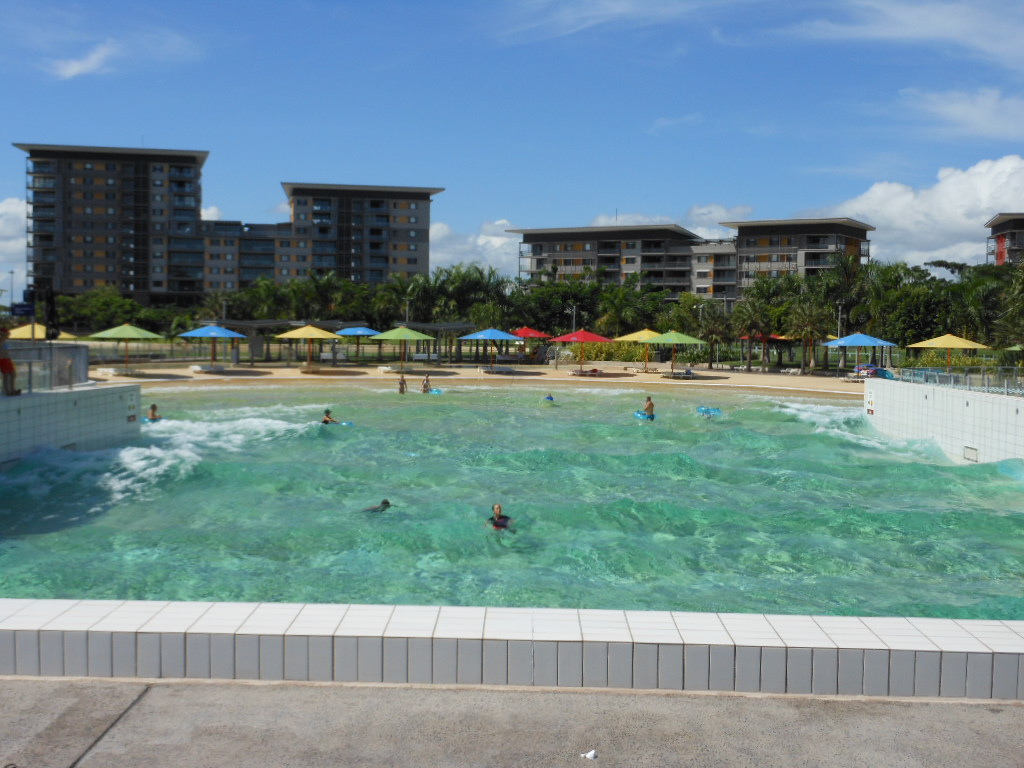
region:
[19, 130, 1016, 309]
vacation hotel building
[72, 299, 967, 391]
colorful open umbrellas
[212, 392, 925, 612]
swimmers in pool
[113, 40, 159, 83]
white clouds in blue sky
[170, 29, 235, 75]
white clouds in blue sky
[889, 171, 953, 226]
white clouds in blue sky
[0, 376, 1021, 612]
large clear swimming area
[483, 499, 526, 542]
swimmer in the water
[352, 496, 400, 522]
swimmer in the water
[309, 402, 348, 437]
swimmer in the water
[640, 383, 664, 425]
swimmer in the water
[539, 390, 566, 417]
swimmer in the water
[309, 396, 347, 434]
swimmer in the water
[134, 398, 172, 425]
swimmer in the water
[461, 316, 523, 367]
colorful beach umbrella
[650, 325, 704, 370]
colorful beach umbrella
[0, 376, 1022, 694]
large outdoor swimming pool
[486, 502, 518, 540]
person swimming in the water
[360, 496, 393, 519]
person swimming in the water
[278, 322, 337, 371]
yellow beach umbrella on the shore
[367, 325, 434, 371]
green beach umbrella on the shore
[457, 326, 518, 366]
blue beach umbrella on the shore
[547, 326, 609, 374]
red beach umbrella on the shore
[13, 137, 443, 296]
large multi story building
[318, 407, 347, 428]
person swimming in the water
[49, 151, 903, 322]
vacation buildings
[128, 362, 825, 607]
people swimming in pool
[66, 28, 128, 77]
white clouds in blue sky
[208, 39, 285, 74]
white clouds in blue sky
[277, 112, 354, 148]
white clouds in blue sky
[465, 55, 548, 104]
white clouds in blue sky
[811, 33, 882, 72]
white clouds in blue sky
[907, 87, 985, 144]
white clouds in blue sky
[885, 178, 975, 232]
white clouds in blue sky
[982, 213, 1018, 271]
A building in a city.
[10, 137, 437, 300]
A building in a city.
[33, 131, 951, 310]
a row of buildings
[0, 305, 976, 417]
umberllas are by water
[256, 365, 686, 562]
people in the water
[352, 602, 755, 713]
the wall is brick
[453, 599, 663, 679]
the brick is white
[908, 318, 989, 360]
the umberlla is yellow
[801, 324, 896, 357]
the umberalla is blue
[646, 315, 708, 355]
the umberalla is green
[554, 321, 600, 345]
the umberalla is red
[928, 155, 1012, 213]
the cloud is white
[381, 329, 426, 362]
A large open umbrella.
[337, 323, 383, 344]
A large open umbrella.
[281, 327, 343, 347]
A large open umbrella.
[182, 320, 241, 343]
A large open umbrella.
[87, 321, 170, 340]
A large open umbrella.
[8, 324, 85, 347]
A large open umbrella.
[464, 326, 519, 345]
A large open umbrella.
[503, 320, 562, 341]
A large open umbrella.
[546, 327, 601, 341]
A large open umbrella.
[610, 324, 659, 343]
A large open umbrella.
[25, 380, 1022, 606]
green clear water in the pool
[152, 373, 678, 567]
people swimming in the pool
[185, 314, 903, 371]
blue umbrellas next to the pool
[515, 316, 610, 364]
red umbrellas next to the pool